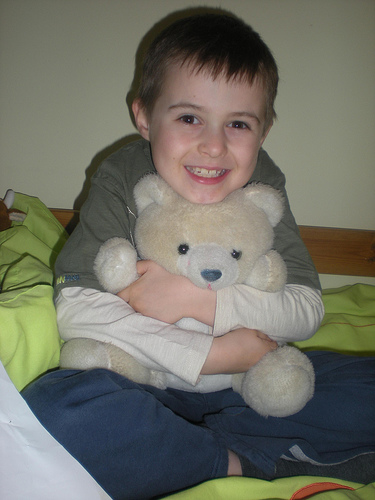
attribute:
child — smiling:
[16, 15, 361, 353]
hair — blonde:
[185, 18, 241, 52]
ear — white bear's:
[132, 174, 171, 213]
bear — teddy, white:
[54, 170, 312, 419]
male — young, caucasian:
[15, 2, 373, 498]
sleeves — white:
[57, 279, 322, 383]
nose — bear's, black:
[198, 268, 226, 281]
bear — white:
[172, 237, 247, 270]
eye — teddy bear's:
[222, 247, 242, 263]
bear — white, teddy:
[88, 178, 299, 321]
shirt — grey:
[61, 140, 136, 253]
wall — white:
[4, 1, 373, 219]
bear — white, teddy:
[126, 171, 314, 289]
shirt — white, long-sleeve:
[51, 281, 323, 383]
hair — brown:
[135, 11, 278, 135]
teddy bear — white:
[60, 174, 315, 416]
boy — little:
[20, 7, 374, 499]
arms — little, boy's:
[51, 138, 324, 373]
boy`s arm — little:
[52, 170, 325, 386]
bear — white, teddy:
[130, 181, 306, 430]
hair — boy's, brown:
[136, 15, 294, 83]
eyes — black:
[165, 235, 200, 274]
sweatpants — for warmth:
[18, 345, 374, 499]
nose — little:
[203, 121, 226, 158]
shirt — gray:
[58, 133, 334, 304]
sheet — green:
[4, 186, 373, 498]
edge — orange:
[289, 481, 355, 498]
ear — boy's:
[132, 98, 150, 140]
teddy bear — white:
[81, 181, 287, 301]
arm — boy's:
[38, 247, 339, 390]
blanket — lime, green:
[2, 187, 371, 423]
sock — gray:
[234, 448, 373, 486]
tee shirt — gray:
[73, 139, 143, 369]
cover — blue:
[1, 314, 363, 490]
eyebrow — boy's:
[171, 100, 205, 113]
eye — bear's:
[230, 246, 244, 263]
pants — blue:
[19, 347, 371, 494]